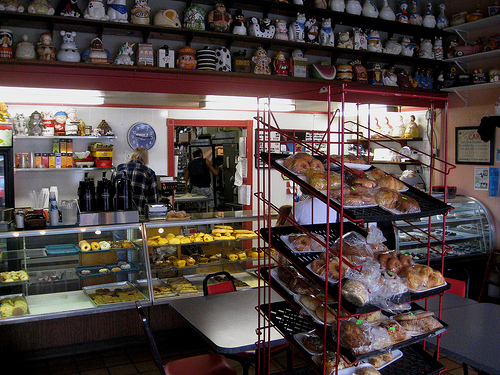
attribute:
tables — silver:
[438, 289, 498, 369]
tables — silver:
[166, 286, 288, 356]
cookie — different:
[158, 225, 235, 255]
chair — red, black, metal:
[138, 270, 270, 374]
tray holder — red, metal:
[257, 120, 432, 367]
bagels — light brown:
[285, 136, 405, 218]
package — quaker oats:
[2, 29, 14, 61]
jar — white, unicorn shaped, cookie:
[115, 43, 135, 69]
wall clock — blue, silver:
[126, 118, 157, 153]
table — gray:
[168, 285, 285, 350]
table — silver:
[167, 264, 499, 359]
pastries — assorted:
[396, 195, 421, 215]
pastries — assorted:
[374, 187, 394, 209]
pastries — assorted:
[376, 173, 404, 193]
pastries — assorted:
[353, 190, 374, 205]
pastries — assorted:
[336, 193, 363, 208]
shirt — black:
[189, 158, 213, 188]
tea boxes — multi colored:
[16, 140, 84, 170]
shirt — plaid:
[111, 156, 192, 199]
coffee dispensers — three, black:
[77, 166, 132, 213]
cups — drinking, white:
[42, 186, 62, 228]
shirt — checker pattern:
[108, 161, 159, 206]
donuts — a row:
[87, 212, 263, 315]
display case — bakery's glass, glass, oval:
[5, 188, 498, 329]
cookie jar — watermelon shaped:
[311, 62, 337, 80]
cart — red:
[265, 131, 435, 368]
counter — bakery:
[2, 195, 497, 318]